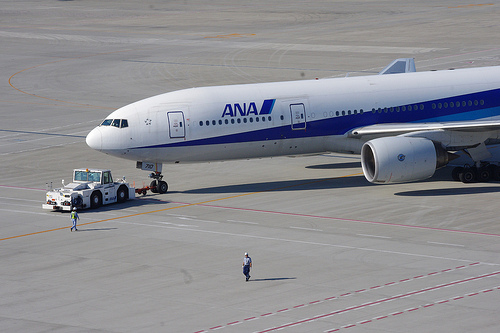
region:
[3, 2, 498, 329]
tarmac surface of airport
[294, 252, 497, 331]
red lines on pavement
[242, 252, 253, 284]
man walking on tarmac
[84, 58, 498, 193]
airplane parked on runway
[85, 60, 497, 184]
white and blue body of plane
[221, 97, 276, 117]
logo on side of plane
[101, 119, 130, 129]
windows on front of plane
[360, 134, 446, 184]
jet engine under wing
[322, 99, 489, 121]
windows on body of plane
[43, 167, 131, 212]
vehicle under nose of plane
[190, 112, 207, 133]
Small window on plate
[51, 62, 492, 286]
Blue and white plane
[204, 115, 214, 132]
Small window on plate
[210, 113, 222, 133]
Small window on plate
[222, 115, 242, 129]
Small window on plate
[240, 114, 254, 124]
Small window on plate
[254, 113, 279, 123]
Small window on plate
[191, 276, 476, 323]
White and red lines on pavement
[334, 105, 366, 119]
Small window on plate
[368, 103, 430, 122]
Small window on plate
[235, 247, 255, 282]
Man walking on tarmac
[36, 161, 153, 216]
Airport guide truck attached to airplane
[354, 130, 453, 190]
Jet engine on airplane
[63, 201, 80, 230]
Man walking on tarmac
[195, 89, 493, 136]
Passenger windows on airplane fuselage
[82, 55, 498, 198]
Jet passenger airplane on tarmac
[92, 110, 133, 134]
Cockpit of jet airplane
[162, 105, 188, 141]
Front egress door on airplane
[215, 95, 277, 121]
Business name and logo of airplane owner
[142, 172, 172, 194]
Front landing gear of airplane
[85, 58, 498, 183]
Blue and white jet airplane parked on the area ramp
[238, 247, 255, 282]
Man walking away from the plane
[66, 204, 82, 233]
Man walking toward the plane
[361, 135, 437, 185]
Left engine of jet plane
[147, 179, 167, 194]
Front wheel of airplane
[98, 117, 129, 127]
Windshield of the cockpit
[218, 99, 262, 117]
airline name on the left side of the plane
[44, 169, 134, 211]
White tow truck for the airplane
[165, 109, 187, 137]
Entrance/exit door of airplane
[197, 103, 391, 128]
Passenger windows on the left side of the plane